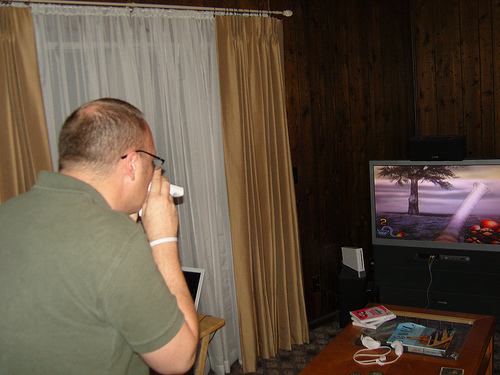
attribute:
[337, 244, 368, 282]
wii — white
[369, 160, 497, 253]
televison — on, flat, wide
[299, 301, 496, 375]
table — red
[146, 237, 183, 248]
band — white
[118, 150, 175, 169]
glasses — black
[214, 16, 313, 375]
curtains — open, beige, closed, gold, sheer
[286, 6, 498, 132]
wood — dark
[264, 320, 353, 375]
carpet — beige, brown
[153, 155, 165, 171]
spectacles — black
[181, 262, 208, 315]
laptop — off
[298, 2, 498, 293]
wall — dark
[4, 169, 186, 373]
shirt — grey, green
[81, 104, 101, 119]
spot — bald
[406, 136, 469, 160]
speaker — black